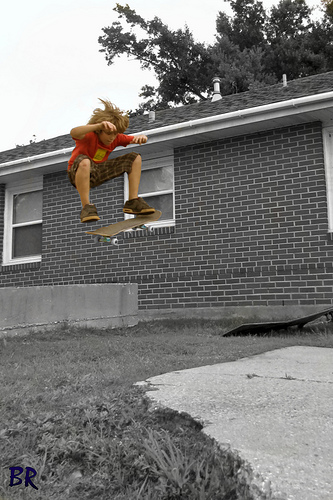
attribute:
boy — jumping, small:
[57, 96, 162, 228]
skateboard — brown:
[84, 202, 164, 247]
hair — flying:
[81, 97, 131, 136]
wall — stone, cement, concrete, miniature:
[1, 281, 146, 340]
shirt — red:
[62, 123, 131, 169]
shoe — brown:
[71, 201, 107, 229]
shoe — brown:
[120, 191, 158, 219]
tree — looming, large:
[91, 1, 332, 121]